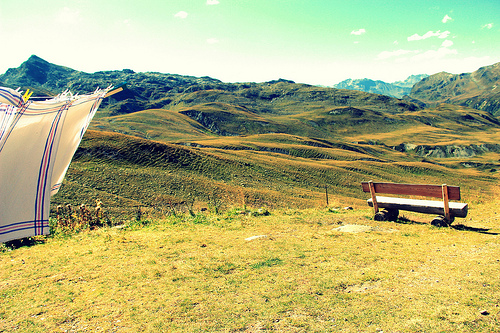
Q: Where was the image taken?
A: It was taken at the field.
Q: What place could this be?
A: It is a field.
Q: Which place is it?
A: It is a field.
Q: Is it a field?
A: Yes, it is a field.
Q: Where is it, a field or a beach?
A: It is a field.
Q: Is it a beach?
A: No, it is a field.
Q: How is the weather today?
A: It is cloudy.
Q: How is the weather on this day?
A: It is cloudy.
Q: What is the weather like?
A: It is cloudy.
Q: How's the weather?
A: It is cloudy.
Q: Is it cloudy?
A: Yes, it is cloudy.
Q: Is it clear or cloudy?
A: It is cloudy.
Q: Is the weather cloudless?
A: No, it is cloudy.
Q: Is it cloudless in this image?
A: No, it is cloudy.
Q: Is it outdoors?
A: Yes, it is outdoors.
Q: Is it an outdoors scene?
A: Yes, it is outdoors.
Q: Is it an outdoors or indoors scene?
A: It is outdoors.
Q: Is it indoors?
A: No, it is outdoors.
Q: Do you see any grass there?
A: Yes, there is grass.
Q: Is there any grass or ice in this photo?
A: Yes, there is grass.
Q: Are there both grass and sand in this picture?
A: No, there is grass but no sand.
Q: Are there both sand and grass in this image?
A: No, there is grass but no sand.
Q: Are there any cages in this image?
A: No, there are no cages.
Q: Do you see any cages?
A: No, there are no cages.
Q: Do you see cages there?
A: No, there are no cages.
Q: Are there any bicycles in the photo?
A: No, there are no bicycles.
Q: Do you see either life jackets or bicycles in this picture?
A: No, there are no bicycles or life jackets.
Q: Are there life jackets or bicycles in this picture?
A: No, there are no bicycles or life jackets.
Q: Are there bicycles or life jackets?
A: No, there are no bicycles or life jackets.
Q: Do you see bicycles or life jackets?
A: No, there are no bicycles or life jackets.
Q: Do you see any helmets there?
A: No, there are no helmets.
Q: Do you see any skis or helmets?
A: No, there are no helmets or skis.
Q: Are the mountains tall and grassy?
A: Yes, the mountains are tall and grassy.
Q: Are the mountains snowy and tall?
A: No, the mountains are tall but grassy.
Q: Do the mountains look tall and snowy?
A: No, the mountains are tall but grassy.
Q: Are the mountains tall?
A: Yes, the mountains are tall.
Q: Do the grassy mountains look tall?
A: Yes, the mountains are tall.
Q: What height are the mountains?
A: The mountains are tall.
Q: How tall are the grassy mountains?
A: The mountains are tall.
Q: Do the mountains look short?
A: No, the mountains are tall.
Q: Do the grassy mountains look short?
A: No, the mountains are tall.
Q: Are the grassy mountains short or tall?
A: The mountains are tall.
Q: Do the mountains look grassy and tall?
A: Yes, the mountains are grassy and tall.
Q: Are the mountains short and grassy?
A: No, the mountains are grassy but tall.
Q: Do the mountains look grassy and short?
A: No, the mountains are grassy but tall.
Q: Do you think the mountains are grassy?
A: Yes, the mountains are grassy.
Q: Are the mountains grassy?
A: Yes, the mountains are grassy.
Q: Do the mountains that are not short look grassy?
A: Yes, the mountains are grassy.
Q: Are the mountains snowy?
A: No, the mountains are grassy.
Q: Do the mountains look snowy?
A: No, the mountains are grassy.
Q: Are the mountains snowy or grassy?
A: The mountains are grassy.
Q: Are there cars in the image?
A: No, there are no cars.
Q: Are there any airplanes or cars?
A: No, there are no cars or airplanes.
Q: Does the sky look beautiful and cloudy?
A: Yes, the sky is beautiful and cloudy.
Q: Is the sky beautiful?
A: Yes, the sky is beautiful.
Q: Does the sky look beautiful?
A: Yes, the sky is beautiful.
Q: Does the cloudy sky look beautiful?
A: Yes, the sky is beautiful.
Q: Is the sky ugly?
A: No, the sky is beautiful.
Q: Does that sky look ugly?
A: No, the sky is beautiful.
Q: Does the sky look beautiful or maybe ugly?
A: The sky is beautiful.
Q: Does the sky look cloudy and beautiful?
A: Yes, the sky is cloudy and beautiful.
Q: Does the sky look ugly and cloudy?
A: No, the sky is cloudy but beautiful.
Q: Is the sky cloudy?
A: Yes, the sky is cloudy.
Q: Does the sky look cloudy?
A: Yes, the sky is cloudy.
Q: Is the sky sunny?
A: No, the sky is cloudy.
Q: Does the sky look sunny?
A: No, the sky is cloudy.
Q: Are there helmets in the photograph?
A: No, there are no helmets.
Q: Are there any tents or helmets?
A: No, there are no helmets or tents.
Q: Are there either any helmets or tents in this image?
A: No, there are no helmets or tents.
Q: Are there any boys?
A: No, there are no boys.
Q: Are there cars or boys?
A: No, there are no boys or cars.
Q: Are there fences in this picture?
A: Yes, there is a fence.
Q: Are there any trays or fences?
A: Yes, there is a fence.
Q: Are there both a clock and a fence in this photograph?
A: No, there is a fence but no clocks.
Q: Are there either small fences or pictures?
A: Yes, there is a small fence.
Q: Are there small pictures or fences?
A: Yes, there is a small fence.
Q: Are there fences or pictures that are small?
A: Yes, the fence is small.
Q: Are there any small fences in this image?
A: Yes, there is a small fence.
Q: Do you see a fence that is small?
A: Yes, there is a fence that is small.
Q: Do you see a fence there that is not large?
A: Yes, there is a small fence.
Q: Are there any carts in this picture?
A: No, there are no carts.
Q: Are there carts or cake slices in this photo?
A: No, there are no carts or cake slices.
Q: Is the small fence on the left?
A: Yes, the fence is on the left of the image.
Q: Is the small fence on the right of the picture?
A: No, the fence is on the left of the image.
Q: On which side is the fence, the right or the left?
A: The fence is on the left of the image.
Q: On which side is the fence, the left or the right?
A: The fence is on the left of the image.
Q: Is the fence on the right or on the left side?
A: The fence is on the left of the image.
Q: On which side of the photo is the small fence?
A: The fence is on the left of the image.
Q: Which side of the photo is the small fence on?
A: The fence is on the left of the image.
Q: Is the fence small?
A: Yes, the fence is small.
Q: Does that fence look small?
A: Yes, the fence is small.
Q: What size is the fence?
A: The fence is small.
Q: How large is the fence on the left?
A: The fence is small.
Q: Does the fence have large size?
A: No, the fence is small.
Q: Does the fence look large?
A: No, the fence is small.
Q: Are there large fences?
A: No, there is a fence but it is small.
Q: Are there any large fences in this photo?
A: No, there is a fence but it is small.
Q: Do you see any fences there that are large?
A: No, there is a fence but it is small.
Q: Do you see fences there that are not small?
A: No, there is a fence but it is small.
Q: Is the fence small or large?
A: The fence is small.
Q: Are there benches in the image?
A: Yes, there is a bench.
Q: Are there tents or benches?
A: Yes, there is a bench.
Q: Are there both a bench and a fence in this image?
A: Yes, there are both a bench and a fence.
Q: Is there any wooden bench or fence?
A: Yes, there is a wood bench.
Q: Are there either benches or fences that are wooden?
A: Yes, the bench is wooden.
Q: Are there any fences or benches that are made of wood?
A: Yes, the bench is made of wood.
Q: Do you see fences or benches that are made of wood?
A: Yes, the bench is made of wood.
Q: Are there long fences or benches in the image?
A: Yes, there is a long bench.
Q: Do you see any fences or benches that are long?
A: Yes, the bench is long.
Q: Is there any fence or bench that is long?
A: Yes, the bench is long.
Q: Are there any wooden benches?
A: Yes, there is a wood bench.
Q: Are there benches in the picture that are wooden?
A: Yes, there is a bench that is wooden.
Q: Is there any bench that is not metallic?
A: Yes, there is a wooden bench.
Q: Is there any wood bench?
A: Yes, there is a bench that is made of wood.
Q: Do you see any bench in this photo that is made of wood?
A: Yes, there is a bench that is made of wood.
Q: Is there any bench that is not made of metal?
A: Yes, there is a bench that is made of wood.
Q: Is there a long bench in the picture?
A: Yes, there is a long bench.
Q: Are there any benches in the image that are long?
A: Yes, there is a bench that is long.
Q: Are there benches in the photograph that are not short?
A: Yes, there is a long bench.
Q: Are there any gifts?
A: No, there are no gifts.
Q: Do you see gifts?
A: No, there are no gifts.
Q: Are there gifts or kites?
A: No, there are no gifts or kites.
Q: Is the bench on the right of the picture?
A: Yes, the bench is on the right of the image.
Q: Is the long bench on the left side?
A: No, the bench is on the right of the image.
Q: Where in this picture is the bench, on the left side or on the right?
A: The bench is on the right of the image.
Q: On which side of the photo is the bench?
A: The bench is on the right of the image.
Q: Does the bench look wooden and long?
A: Yes, the bench is wooden and long.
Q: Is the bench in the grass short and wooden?
A: No, the bench is wooden but long.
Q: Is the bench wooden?
A: Yes, the bench is wooden.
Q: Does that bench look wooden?
A: Yes, the bench is wooden.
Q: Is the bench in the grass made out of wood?
A: Yes, the bench is made of wood.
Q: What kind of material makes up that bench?
A: The bench is made of wood.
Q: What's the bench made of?
A: The bench is made of wood.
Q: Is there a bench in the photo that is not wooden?
A: No, there is a bench but it is wooden.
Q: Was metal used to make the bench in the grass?
A: No, the bench is made of wood.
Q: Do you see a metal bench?
A: No, there is a bench but it is made of wood.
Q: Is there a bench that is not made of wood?
A: No, there is a bench but it is made of wood.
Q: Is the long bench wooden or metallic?
A: The bench is wooden.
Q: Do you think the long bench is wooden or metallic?
A: The bench is wooden.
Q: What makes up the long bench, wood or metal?
A: The bench is made of wood.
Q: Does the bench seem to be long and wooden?
A: Yes, the bench is long and wooden.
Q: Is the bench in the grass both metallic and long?
A: No, the bench is long but wooden.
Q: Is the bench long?
A: Yes, the bench is long.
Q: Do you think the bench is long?
A: Yes, the bench is long.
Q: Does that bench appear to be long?
A: Yes, the bench is long.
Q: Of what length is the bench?
A: The bench is long.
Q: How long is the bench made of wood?
A: The bench is long.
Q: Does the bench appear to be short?
A: No, the bench is long.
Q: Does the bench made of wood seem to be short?
A: No, the bench is long.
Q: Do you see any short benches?
A: No, there is a bench but it is long.